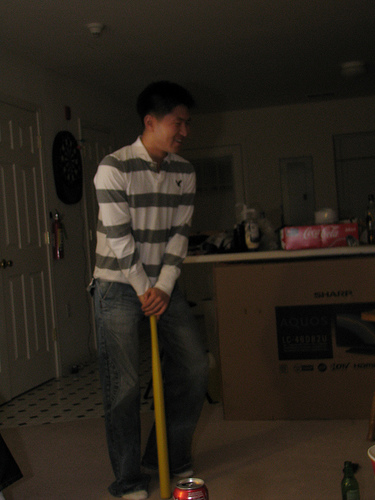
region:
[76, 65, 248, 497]
a tall Asian man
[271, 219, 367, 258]
a box of soda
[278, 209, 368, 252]
a Coca Cola box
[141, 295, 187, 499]
a yellow bat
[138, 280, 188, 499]
a wiffle ball bat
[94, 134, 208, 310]
a long sleeved shirt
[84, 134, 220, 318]
the shirt has white and grey stripes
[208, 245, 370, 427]
a large box for a television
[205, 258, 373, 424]
a flat screen tv box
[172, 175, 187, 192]
logo on the shirt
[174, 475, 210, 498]
Red soda can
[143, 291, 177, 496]
Man holding baseball bat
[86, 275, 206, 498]
Man wearing blue jeans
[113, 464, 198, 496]
Man wearing white socks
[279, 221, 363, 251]
Box of soda on counter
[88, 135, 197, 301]
Man wearing long sleeved shirt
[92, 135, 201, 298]
Man wearing gray and white striped long sleeve shirt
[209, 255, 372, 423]
Television box on the floor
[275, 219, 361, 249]
Box of Coca Cola on the counter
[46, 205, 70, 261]
Fire hydrant hanging on the wall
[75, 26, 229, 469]
man is wearing jeans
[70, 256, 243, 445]
the jeans are blue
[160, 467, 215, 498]
a can of soda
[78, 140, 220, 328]
man is wearing striped shirt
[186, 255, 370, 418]
big box under counter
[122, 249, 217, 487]
man is holding a bat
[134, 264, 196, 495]
the bat is yellow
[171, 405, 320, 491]
the floor is beige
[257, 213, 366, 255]
a red box on the counter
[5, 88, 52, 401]
the door is closed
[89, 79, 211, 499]
young asian boy with baseball bat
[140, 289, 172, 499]
someone holding a bat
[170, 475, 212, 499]
soda can sitting near boy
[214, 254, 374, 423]
box from new Sharp TV box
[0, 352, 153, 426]
linoleum in kitchen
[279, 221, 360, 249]
box of Coca-Cola on the bar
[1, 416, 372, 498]
beige rug in the living room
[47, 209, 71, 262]
fire hydrant on the wall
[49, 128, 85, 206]
dart board on the wall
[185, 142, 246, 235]
window in the kitchen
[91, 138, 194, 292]
the man is wearing a long sleeve shirt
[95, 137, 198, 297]
the shirt has black and white stripes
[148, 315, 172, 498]
the man is holding a stick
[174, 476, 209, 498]
a soda can is in front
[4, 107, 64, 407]
a door is behind the man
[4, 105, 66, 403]
the door is white in color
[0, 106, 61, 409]
the door is made of wood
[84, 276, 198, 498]
the man is wearing jeans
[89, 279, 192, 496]
the jeans are blue in color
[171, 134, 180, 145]
the man is smiling